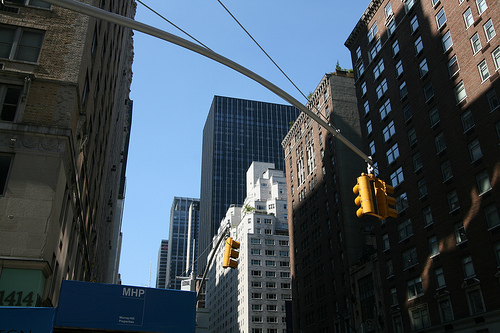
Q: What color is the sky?
A: Blue.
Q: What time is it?
A: Afternoon.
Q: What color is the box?
A: Blue.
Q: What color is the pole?
A: Silver.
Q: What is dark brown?
A: The building.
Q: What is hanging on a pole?
A: A traffic light.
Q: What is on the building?
A: Windows.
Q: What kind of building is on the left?
A: Brick.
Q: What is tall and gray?
A: One of the buildings.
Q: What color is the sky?
A: Blue.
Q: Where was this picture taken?
A: Downtown.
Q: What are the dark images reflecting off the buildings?
A: Shadows.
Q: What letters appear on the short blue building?
A: MHP.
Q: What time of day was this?
A: Afternoon.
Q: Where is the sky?
A: Above the buildings.